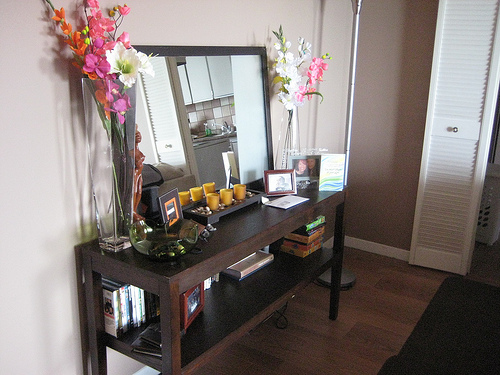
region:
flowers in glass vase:
[59, 6, 160, 259]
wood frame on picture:
[253, 165, 306, 202]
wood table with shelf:
[113, 162, 361, 365]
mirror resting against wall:
[90, 29, 294, 199]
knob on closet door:
[437, 117, 468, 156]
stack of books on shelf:
[284, 211, 334, 265]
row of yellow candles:
[199, 173, 260, 221]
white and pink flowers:
[275, 48, 331, 111]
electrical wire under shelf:
[264, 300, 308, 337]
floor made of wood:
[352, 270, 416, 333]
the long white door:
[395, 2, 498, 293]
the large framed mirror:
[117, 47, 277, 216]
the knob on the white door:
[445, 123, 465, 140]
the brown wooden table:
[75, 189, 380, 374]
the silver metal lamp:
[315, 2, 373, 291]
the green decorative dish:
[128, 218, 207, 269]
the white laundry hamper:
[472, 156, 498, 251]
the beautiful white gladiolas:
[265, 24, 301, 115]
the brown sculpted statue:
[130, 122, 150, 237]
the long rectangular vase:
[76, 75, 140, 257]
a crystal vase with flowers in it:
[39, 1, 154, 252]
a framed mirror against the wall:
[105, 43, 275, 210]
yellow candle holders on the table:
[233, 183, 247, 203]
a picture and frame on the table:
[265, 168, 296, 194]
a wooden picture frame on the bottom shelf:
[179, 281, 205, 328]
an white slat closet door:
[410, 0, 498, 277]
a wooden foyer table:
[75, 177, 347, 374]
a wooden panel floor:
[344, 244, 426, 320]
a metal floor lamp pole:
[321, 1, 363, 289]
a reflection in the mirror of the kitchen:
[168, 55, 237, 189]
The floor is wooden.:
[202, 311, 410, 373]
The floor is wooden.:
[320, 280, 367, 370]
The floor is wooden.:
[334, 304, 352, 365]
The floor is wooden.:
[345, 312, 370, 369]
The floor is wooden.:
[287, 208, 362, 370]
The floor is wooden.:
[391, 267, 418, 359]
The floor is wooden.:
[340, 277, 360, 374]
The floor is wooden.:
[362, 232, 406, 334]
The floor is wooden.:
[341, 262, 391, 370]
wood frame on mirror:
[182, 34, 279, 63]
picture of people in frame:
[285, 147, 329, 183]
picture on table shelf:
[173, 276, 209, 338]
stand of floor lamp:
[311, 253, 359, 290]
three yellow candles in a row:
[199, 176, 254, 217]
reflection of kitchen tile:
[192, 87, 243, 132]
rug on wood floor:
[399, 273, 463, 346]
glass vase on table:
[89, 197, 146, 264]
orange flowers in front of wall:
[49, 5, 87, 56]